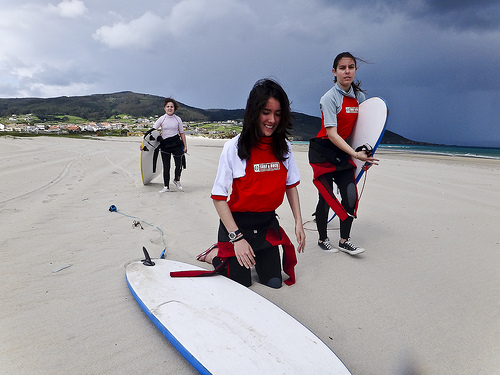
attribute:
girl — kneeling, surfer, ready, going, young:
[210, 76, 311, 294]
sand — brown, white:
[3, 131, 499, 374]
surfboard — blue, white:
[117, 242, 354, 374]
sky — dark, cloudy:
[1, 1, 499, 152]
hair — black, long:
[235, 73, 298, 166]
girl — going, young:
[302, 45, 382, 265]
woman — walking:
[153, 95, 192, 196]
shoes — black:
[315, 232, 339, 256]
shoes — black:
[337, 238, 366, 258]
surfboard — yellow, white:
[138, 124, 161, 190]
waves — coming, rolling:
[379, 144, 499, 160]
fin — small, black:
[138, 242, 155, 268]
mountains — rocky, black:
[0, 89, 419, 146]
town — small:
[1, 109, 292, 145]